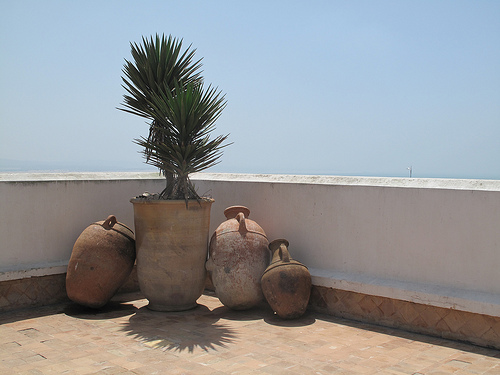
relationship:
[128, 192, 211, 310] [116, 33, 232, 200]
pot has plant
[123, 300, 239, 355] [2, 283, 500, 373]
shadow across ground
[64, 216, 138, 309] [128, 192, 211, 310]
pot next to pot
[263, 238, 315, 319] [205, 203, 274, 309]
pot next to pot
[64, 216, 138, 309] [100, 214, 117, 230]
pot has handle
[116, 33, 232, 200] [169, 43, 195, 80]
plant has leaf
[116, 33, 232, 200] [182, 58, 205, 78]
plant has leaf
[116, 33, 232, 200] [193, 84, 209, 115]
plant has leaf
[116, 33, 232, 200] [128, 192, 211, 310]
plant inside pot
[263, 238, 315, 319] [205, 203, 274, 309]
pot leaning against pot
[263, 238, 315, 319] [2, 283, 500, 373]
pot sitting on ground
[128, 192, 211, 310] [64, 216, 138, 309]
pot in between pot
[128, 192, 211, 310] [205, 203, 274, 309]
pot in between pot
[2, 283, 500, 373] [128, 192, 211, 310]
ground under pot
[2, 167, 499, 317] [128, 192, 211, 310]
wall behind pot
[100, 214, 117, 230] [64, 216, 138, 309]
handle on top of pot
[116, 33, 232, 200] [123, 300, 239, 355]
plant casting shadow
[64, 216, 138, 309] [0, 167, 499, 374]
pot sitting on balcony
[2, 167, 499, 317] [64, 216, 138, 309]
wall next to pot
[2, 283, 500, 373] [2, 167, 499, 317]
ground next to wall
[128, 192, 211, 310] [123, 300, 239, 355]
pot has shadow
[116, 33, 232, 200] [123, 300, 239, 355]
plant has shadow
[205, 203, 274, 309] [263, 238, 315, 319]
pot next to pot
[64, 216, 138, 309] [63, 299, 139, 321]
pot has shadow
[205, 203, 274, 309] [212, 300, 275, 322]
pot has shadow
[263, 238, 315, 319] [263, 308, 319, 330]
pot has shadow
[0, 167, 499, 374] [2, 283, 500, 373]
balcony has ground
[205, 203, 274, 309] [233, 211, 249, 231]
pot has handle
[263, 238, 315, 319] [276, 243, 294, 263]
pot has handle